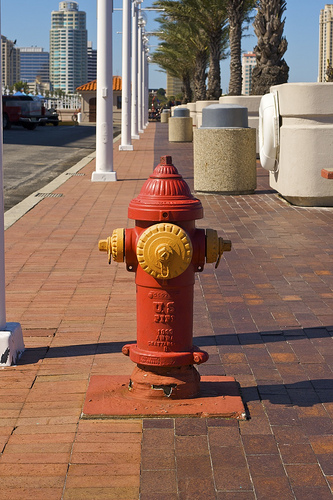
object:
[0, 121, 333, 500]
sidewalk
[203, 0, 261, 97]
tree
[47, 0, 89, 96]
building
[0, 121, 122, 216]
road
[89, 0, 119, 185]
light pole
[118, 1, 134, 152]
light pole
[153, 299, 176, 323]
text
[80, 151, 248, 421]
fire hydrant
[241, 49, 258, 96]
tall building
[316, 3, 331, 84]
tall building